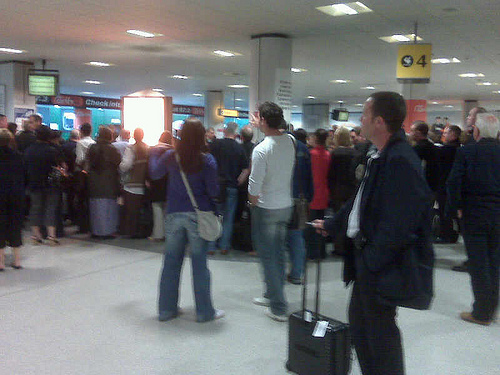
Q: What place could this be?
A: It is an airport.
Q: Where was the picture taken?
A: It was taken at the airport.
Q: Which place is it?
A: It is an airport.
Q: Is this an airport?
A: Yes, it is an airport.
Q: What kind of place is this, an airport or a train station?
A: It is an airport.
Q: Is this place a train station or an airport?
A: It is an airport.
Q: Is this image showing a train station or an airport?
A: It is showing an airport.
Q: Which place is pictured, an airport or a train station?
A: It is an airport.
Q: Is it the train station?
A: No, it is the airport.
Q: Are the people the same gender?
A: No, they are both male and female.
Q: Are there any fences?
A: No, there are no fences.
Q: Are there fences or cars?
A: No, there are no fences or cars.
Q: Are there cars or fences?
A: No, there are no fences or cars.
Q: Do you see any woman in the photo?
A: Yes, there is a woman.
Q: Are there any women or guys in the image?
A: Yes, there is a woman.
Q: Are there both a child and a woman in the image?
A: No, there is a woman but no children.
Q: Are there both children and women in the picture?
A: No, there is a woman but no children.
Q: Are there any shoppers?
A: No, there are no shoppers.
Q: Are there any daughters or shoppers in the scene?
A: No, there are no shoppers or daughters.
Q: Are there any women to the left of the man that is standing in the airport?
A: Yes, there is a woman to the left of the man.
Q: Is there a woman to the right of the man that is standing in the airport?
A: No, the woman is to the left of the man.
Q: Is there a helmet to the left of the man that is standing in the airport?
A: No, there is a woman to the left of the man.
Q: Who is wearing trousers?
A: The woman is wearing trousers.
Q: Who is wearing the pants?
A: The woman is wearing trousers.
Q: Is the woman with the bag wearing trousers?
A: Yes, the woman is wearing trousers.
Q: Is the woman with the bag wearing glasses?
A: No, the woman is wearing trousers.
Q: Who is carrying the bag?
A: The woman is carrying the bag.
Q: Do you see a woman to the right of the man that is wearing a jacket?
A: No, the woman is to the left of the man.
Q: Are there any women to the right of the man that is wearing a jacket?
A: No, the woman is to the left of the man.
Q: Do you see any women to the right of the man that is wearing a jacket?
A: No, the woman is to the left of the man.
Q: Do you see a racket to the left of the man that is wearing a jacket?
A: No, there is a woman to the left of the man.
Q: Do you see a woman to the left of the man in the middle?
A: Yes, there is a woman to the left of the man.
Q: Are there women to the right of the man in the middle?
A: No, the woman is to the left of the man.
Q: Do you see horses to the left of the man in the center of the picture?
A: No, there is a woman to the left of the man.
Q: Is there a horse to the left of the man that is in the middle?
A: No, there is a woman to the left of the man.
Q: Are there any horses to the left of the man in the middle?
A: No, there is a woman to the left of the man.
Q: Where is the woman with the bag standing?
A: The woman is standing in the airport.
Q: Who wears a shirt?
A: The woman wears a shirt.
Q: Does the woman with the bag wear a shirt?
A: Yes, the woman wears a shirt.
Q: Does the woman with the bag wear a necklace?
A: No, the woman wears a shirt.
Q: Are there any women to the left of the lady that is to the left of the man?
A: Yes, there is a woman to the left of the lady.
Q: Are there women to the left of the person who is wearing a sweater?
A: Yes, there is a woman to the left of the lady.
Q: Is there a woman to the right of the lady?
A: No, the woman is to the left of the lady.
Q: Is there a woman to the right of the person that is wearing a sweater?
A: No, the woman is to the left of the lady.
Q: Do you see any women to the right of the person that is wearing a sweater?
A: No, the woman is to the left of the lady.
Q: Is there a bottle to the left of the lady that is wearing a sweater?
A: No, there is a woman to the left of the lady.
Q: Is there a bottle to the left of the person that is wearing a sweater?
A: No, there is a woman to the left of the lady.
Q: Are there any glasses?
A: No, there are no glasses.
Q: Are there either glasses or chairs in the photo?
A: No, there are no glasses or chairs.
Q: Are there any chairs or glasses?
A: No, there are no glasses or chairs.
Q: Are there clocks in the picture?
A: No, there are no clocks.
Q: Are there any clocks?
A: No, there are no clocks.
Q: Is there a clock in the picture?
A: No, there are no clocks.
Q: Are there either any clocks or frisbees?
A: No, there are no clocks or frisbees.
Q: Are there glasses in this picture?
A: No, there are no glasses.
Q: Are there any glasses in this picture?
A: No, there are no glasses.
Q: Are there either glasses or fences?
A: No, there are no glasses or fences.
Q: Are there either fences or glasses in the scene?
A: No, there are no glasses or fences.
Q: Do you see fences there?
A: No, there are no fences.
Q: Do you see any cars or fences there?
A: No, there are no fences or cars.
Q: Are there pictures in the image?
A: No, there are no pictures.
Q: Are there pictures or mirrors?
A: No, there are no pictures or mirrors.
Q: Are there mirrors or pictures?
A: No, there are no pictures or mirrors.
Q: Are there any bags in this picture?
A: Yes, there is a bag.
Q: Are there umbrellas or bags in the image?
A: Yes, there is a bag.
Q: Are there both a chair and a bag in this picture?
A: No, there is a bag but no chairs.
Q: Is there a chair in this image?
A: No, there are no chairs.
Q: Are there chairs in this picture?
A: No, there are no chairs.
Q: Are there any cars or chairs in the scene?
A: No, there are no chairs or cars.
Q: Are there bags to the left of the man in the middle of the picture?
A: Yes, there is a bag to the left of the man.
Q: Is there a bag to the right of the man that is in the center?
A: No, the bag is to the left of the man.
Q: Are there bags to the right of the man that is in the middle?
A: No, the bag is to the left of the man.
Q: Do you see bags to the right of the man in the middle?
A: No, the bag is to the left of the man.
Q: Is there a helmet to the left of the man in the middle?
A: No, there is a bag to the left of the man.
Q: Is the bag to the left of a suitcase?
A: No, the bag is to the left of a man.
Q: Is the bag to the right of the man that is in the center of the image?
A: No, the bag is to the left of the man.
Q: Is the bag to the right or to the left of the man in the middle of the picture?
A: The bag is to the left of the man.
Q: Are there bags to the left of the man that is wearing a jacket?
A: Yes, there is a bag to the left of the man.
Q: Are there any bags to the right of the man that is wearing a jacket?
A: No, the bag is to the left of the man.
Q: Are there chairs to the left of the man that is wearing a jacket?
A: No, there is a bag to the left of the man.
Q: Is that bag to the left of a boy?
A: No, the bag is to the left of a man.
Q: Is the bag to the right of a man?
A: No, the bag is to the left of a man.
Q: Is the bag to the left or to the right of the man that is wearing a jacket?
A: The bag is to the left of the man.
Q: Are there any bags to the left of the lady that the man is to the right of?
A: Yes, there is a bag to the left of the lady.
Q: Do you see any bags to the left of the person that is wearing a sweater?
A: Yes, there is a bag to the left of the lady.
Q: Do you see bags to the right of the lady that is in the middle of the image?
A: No, the bag is to the left of the lady.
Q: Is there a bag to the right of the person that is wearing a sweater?
A: No, the bag is to the left of the lady.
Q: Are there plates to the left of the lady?
A: No, there is a bag to the left of the lady.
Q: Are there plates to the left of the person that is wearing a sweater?
A: No, there is a bag to the left of the lady.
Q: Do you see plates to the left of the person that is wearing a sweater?
A: No, there is a bag to the left of the lady.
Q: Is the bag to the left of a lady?
A: Yes, the bag is to the left of a lady.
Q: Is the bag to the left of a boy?
A: No, the bag is to the left of a lady.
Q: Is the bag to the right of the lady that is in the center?
A: No, the bag is to the left of the lady.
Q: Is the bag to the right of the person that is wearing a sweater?
A: No, the bag is to the left of the lady.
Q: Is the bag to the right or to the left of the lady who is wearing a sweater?
A: The bag is to the left of the lady.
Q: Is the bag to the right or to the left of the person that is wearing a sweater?
A: The bag is to the left of the lady.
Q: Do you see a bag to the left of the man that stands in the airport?
A: Yes, there is a bag to the left of the man.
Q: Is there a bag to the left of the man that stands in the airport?
A: Yes, there is a bag to the left of the man.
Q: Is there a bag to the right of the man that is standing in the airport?
A: No, the bag is to the left of the man.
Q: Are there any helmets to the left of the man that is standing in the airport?
A: No, there is a bag to the left of the man.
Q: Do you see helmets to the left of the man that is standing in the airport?
A: No, there is a bag to the left of the man.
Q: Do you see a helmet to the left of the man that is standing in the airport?
A: No, there is a bag to the left of the man.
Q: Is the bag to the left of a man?
A: Yes, the bag is to the left of a man.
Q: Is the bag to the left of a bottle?
A: No, the bag is to the left of a man.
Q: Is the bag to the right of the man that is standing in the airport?
A: No, the bag is to the left of the man.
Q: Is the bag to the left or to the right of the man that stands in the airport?
A: The bag is to the left of the man.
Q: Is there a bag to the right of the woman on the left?
A: Yes, there is a bag to the right of the woman.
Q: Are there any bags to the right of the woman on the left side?
A: Yes, there is a bag to the right of the woman.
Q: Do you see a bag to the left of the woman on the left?
A: No, the bag is to the right of the woman.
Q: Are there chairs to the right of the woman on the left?
A: No, there is a bag to the right of the woman.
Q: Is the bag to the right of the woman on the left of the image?
A: Yes, the bag is to the right of the woman.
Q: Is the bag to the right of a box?
A: No, the bag is to the right of the woman.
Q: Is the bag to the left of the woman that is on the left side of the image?
A: No, the bag is to the right of the woman.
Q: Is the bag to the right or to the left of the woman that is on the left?
A: The bag is to the right of the woman.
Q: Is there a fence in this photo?
A: No, there are no fences.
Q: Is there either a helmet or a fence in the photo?
A: No, there are no fences or helmets.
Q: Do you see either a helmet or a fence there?
A: No, there are no fences or helmets.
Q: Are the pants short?
A: Yes, the pants are short.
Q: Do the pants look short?
A: Yes, the pants are short.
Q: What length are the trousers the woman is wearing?
A: The pants are short.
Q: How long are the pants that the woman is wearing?
A: The pants are short.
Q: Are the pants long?
A: No, the pants are short.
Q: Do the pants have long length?
A: No, the pants are short.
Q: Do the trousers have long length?
A: No, the trousers are short.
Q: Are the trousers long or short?
A: The trousers are short.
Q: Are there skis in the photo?
A: No, there are no skis.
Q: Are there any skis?
A: No, there are no skis.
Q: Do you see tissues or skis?
A: No, there are no skis or tissues.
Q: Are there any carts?
A: No, there are no carts.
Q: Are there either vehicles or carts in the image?
A: No, there are no carts or vehicles.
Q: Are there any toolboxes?
A: No, there are no toolboxes.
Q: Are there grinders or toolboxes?
A: No, there are no toolboxes or grinders.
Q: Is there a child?
A: No, there are no children.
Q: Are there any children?
A: No, there are no children.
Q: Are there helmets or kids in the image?
A: No, there are no kids or helmets.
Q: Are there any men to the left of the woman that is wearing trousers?
A: No, the man is to the right of the woman.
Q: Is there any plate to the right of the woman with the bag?
A: No, there is a man to the right of the woman.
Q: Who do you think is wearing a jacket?
A: The man is wearing a jacket.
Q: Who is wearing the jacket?
A: The man is wearing a jacket.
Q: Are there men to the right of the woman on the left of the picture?
A: Yes, there is a man to the right of the woman.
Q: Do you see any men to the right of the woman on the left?
A: Yes, there is a man to the right of the woman.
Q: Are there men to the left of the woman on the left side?
A: No, the man is to the right of the woman.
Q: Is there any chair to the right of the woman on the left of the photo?
A: No, there is a man to the right of the woman.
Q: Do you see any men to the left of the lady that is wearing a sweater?
A: Yes, there is a man to the left of the lady.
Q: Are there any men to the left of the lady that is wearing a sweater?
A: Yes, there is a man to the left of the lady.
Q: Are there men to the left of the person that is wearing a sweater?
A: Yes, there is a man to the left of the lady.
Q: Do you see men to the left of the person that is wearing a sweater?
A: Yes, there is a man to the left of the lady.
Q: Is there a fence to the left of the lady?
A: No, there is a man to the left of the lady.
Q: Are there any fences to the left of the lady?
A: No, there is a man to the left of the lady.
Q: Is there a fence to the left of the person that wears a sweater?
A: No, there is a man to the left of the lady.